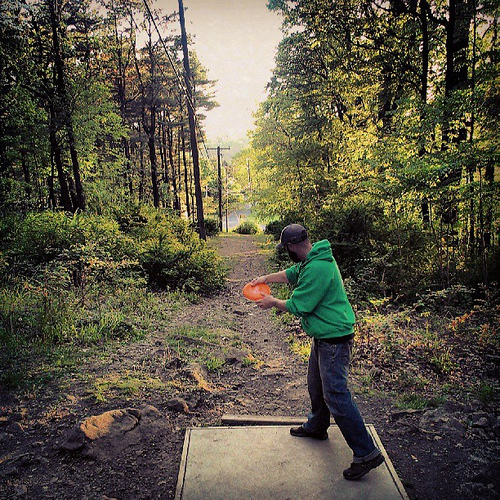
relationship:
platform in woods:
[141, 391, 441, 498] [0, 0, 498, 499]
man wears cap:
[249, 224, 384, 483] [274, 224, 309, 251]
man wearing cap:
[219, 193, 417, 492] [261, 214, 316, 242]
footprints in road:
[82, 409, 137, 441] [218, 232, 255, 271]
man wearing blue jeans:
[249, 224, 384, 483] [297, 328, 385, 466]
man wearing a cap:
[249, 224, 384, 483] [275, 215, 312, 249]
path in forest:
[219, 235, 276, 415] [0, 1, 499, 391]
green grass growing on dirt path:
[166, 316, 259, 376] [139, 315, 291, 406]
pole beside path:
[212, 148, 232, 215] [232, 233, 260, 270]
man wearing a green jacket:
[249, 224, 384, 483] [280, 237, 357, 342]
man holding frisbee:
[249, 224, 384, 483] [230, 257, 292, 337]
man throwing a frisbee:
[249, 224, 384, 483] [239, 277, 271, 303]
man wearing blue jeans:
[249, 224, 384, 483] [296, 334, 383, 471]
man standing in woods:
[249, 224, 384, 483] [0, 0, 498, 499]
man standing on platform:
[249, 224, 384, 483] [175, 422, 409, 499]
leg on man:
[314, 336, 380, 463] [249, 224, 384, 483]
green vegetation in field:
[3, 288, 66, 341] [60, 87, 468, 277]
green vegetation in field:
[472, 380, 494, 406] [60, 87, 468, 277]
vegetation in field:
[24, 207, 141, 289] [60, 87, 468, 277]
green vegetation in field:
[136, 217, 227, 295] [60, 87, 468, 277]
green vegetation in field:
[232, 220, 259, 234] [60, 87, 468, 277]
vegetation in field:
[24, 207, 140, 255] [43, 68, 483, 238]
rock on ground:
[60, 393, 179, 468] [66, 342, 174, 494]